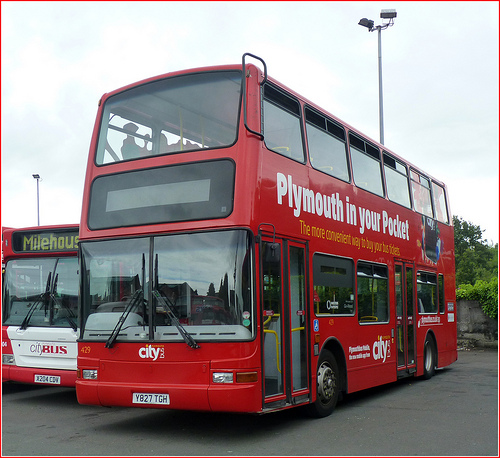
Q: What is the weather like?
A: It is cloudy.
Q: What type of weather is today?
A: It is cloudy.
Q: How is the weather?
A: It is cloudy.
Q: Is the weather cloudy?
A: Yes, it is cloudy.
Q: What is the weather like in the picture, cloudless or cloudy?
A: It is cloudy.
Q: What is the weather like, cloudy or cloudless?
A: It is cloudy.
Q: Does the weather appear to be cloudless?
A: No, it is cloudy.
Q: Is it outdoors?
A: Yes, it is outdoors.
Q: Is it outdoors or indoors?
A: It is outdoors.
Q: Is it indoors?
A: No, it is outdoors.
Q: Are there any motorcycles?
A: No, there are no motorcycles.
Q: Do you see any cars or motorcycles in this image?
A: No, there are no motorcycles or cars.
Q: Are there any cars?
A: No, there are no cars.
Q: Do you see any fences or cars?
A: No, there are no cars or fences.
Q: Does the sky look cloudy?
A: Yes, the sky is cloudy.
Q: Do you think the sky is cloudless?
A: No, the sky is cloudy.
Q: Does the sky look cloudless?
A: No, the sky is cloudy.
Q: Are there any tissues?
A: No, there are no tissues.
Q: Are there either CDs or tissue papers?
A: No, there are no tissue papers or cds.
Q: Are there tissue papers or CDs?
A: No, there are no tissue papers or cds.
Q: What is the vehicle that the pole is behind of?
A: The vehicle is a bus.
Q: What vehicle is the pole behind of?
A: The pole is behind the bus.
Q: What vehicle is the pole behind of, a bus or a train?
A: The pole is behind a bus.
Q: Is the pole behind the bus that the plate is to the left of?
A: Yes, the pole is behind the bus.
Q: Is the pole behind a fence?
A: No, the pole is behind the bus.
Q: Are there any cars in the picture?
A: No, there are no cars.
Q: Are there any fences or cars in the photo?
A: No, there are no cars or fences.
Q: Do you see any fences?
A: No, there are no fences.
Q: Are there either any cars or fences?
A: No, there are no fences or cars.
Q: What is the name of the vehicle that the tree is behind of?
A: The vehicle is a bus.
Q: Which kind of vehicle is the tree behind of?
A: The tree is behind the bus.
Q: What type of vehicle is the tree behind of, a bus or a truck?
A: The tree is behind a bus.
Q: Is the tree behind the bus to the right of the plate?
A: Yes, the tree is behind the bus.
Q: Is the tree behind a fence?
A: No, the tree is behind the bus.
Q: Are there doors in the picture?
A: Yes, there is a door.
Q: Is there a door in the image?
A: Yes, there is a door.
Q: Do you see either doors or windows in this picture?
A: Yes, there is a door.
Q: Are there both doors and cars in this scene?
A: No, there is a door but no cars.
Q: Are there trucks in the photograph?
A: No, there are no trucks.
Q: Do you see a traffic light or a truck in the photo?
A: No, there are no trucks or traffic lights.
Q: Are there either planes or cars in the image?
A: No, there are no cars or planes.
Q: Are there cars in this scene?
A: No, there are no cars.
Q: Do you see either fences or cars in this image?
A: No, there are no cars or fences.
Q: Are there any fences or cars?
A: No, there are no cars or fences.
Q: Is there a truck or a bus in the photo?
A: Yes, there is a bus.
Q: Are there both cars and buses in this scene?
A: No, there is a bus but no cars.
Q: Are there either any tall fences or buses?
A: Yes, there is a tall bus.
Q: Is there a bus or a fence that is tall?
A: Yes, the bus is tall.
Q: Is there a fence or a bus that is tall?
A: Yes, the bus is tall.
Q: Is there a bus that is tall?
A: Yes, there is a tall bus.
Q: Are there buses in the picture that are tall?
A: Yes, there is a bus that is tall.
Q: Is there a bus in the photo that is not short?
A: Yes, there is a tall bus.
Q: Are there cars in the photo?
A: No, there are no cars.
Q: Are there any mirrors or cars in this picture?
A: No, there are no cars or mirrors.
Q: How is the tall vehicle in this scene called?
A: The vehicle is a bus.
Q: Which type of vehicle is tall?
A: The vehicle is a bus.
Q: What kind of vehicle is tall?
A: The vehicle is a bus.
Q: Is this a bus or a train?
A: This is a bus.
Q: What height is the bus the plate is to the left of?
A: The bus is tall.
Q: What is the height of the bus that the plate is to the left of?
A: The bus is tall.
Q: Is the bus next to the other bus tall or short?
A: The bus is tall.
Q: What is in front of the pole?
A: The bus is in front of the pole.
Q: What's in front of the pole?
A: The bus is in front of the pole.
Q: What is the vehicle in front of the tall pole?
A: The vehicle is a bus.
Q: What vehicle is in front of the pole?
A: The vehicle is a bus.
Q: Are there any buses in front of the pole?
A: Yes, there is a bus in front of the pole.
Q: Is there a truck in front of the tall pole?
A: No, there is a bus in front of the pole.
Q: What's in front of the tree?
A: The bus is in front of the tree.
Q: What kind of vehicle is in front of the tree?
A: The vehicle is a bus.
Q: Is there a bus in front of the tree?
A: Yes, there is a bus in front of the tree.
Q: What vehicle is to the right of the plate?
A: The vehicle is a bus.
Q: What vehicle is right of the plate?
A: The vehicle is a bus.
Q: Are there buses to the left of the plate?
A: No, the bus is to the right of the plate.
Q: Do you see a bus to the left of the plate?
A: No, the bus is to the right of the plate.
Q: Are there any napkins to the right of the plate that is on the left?
A: No, there is a bus to the right of the plate.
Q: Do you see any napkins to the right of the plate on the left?
A: No, there is a bus to the right of the plate.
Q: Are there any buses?
A: Yes, there is a bus.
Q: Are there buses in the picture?
A: Yes, there is a bus.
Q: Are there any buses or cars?
A: Yes, there is a bus.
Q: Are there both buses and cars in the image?
A: No, there is a bus but no cars.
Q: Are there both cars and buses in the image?
A: No, there is a bus but no cars.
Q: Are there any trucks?
A: No, there are no trucks.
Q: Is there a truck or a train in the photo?
A: No, there are no trucks or trains.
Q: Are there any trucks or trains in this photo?
A: No, there are no trucks or trains.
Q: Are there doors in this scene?
A: Yes, there is a door.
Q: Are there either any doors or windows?
A: Yes, there is a door.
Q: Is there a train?
A: No, there are no trains.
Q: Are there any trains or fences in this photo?
A: No, there are no trains or fences.